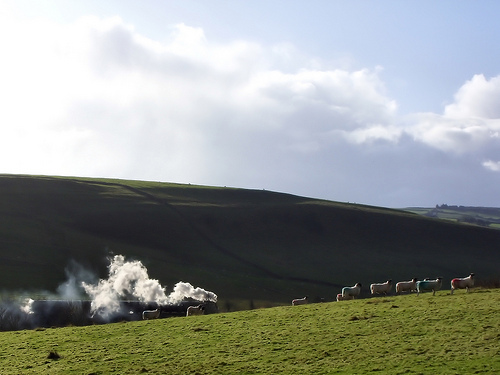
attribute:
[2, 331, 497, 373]
field — grassy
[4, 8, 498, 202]
clouds — white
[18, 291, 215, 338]
train — black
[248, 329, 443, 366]
grass — green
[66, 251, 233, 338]
steam — gray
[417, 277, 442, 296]
animal — blue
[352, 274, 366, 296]
bleack head — small, black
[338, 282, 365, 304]
sheep — white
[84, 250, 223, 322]
steam — thick, white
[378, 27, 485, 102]
sky — blue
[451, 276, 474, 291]
butt — red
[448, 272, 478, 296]
sheep — white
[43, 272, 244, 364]
train — black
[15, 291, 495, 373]
grass — bright, green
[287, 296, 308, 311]
animal — white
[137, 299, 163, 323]
animal — white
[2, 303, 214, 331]
train — black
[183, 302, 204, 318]
sheep — white, standing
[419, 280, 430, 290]
marking — blue